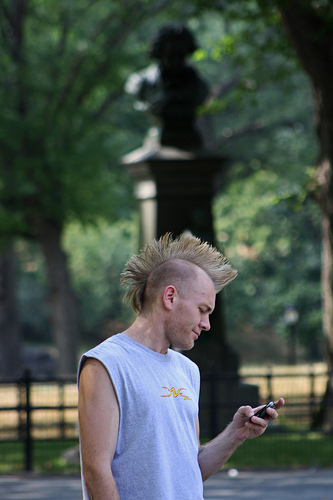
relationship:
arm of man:
[68, 358, 127, 498] [73, 232, 286, 498]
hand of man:
[231, 396, 286, 443] [86, 363, 146, 491]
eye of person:
[198, 305, 207, 314] [44, 206, 293, 498]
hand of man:
[201, 402, 280, 480] [77, 230, 284, 500]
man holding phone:
[77, 230, 284, 500] [244, 401, 275, 420]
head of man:
[121, 230, 238, 352] [73, 232, 286, 498]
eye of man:
[198, 305, 207, 315] [58, 219, 267, 487]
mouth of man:
[186, 324, 201, 341] [73, 232, 286, 498]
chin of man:
[168, 328, 211, 356] [73, 209, 270, 367]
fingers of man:
[239, 396, 285, 431] [73, 232, 286, 498]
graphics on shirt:
[160, 386, 192, 401] [79, 330, 203, 499]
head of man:
[121, 230, 238, 352] [77, 230, 284, 500]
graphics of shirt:
[153, 382, 194, 407] [69, 330, 216, 498]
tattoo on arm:
[197, 444, 204, 453] [192, 419, 234, 483]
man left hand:
[73, 232, 286, 498] [233, 396, 283, 437]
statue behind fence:
[111, 13, 266, 431] [2, 358, 332, 442]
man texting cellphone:
[73, 232, 286, 498] [245, 399, 273, 420]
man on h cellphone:
[73, 232, 286, 498] [245, 399, 273, 420]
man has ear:
[73, 232, 286, 498] [158, 279, 178, 314]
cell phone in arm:
[248, 401, 275, 424] [201, 395, 287, 483]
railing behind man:
[1, 377, 332, 482] [73, 232, 286, 498]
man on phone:
[77, 230, 284, 500] [236, 388, 288, 414]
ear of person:
[158, 279, 178, 314] [33, 228, 298, 497]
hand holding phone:
[231, 396, 286, 443] [245, 401, 279, 421]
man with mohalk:
[73, 232, 286, 498] [94, 224, 252, 354]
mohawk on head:
[103, 229, 250, 324] [126, 214, 234, 347]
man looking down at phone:
[77, 230, 284, 500] [227, 377, 288, 449]